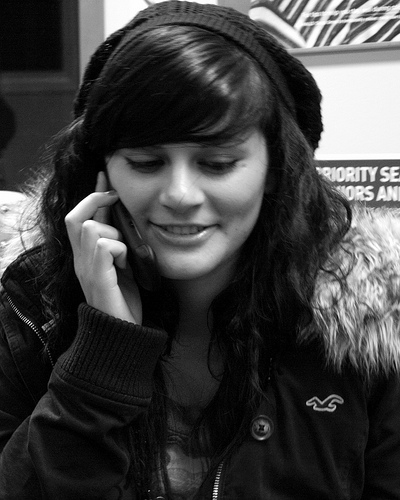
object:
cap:
[71, 0, 324, 159]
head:
[89, 22, 270, 282]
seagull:
[304, 394, 345, 413]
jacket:
[0, 235, 399, 500]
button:
[249, 414, 274, 443]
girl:
[0, 0, 399, 500]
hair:
[13, 23, 354, 480]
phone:
[107, 188, 162, 293]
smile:
[140, 207, 223, 249]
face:
[103, 116, 269, 281]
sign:
[314, 159, 400, 209]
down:
[1, 423, 400, 500]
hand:
[63, 169, 143, 328]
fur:
[292, 203, 398, 376]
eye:
[195, 153, 237, 176]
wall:
[0, 0, 400, 210]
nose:
[159, 149, 206, 215]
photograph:
[0, 0, 400, 500]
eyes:
[123, 153, 164, 175]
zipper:
[209, 450, 227, 500]